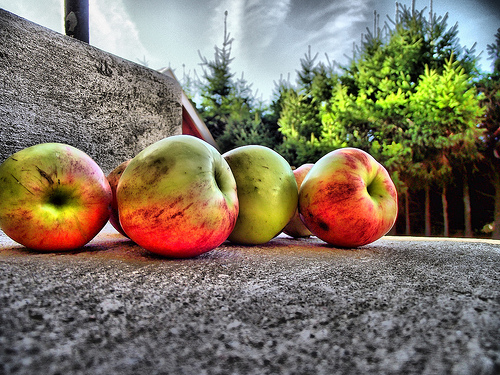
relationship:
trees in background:
[181, 1, 498, 241] [3, 0, 498, 238]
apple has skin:
[221, 145, 298, 246] [222, 143, 298, 247]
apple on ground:
[221, 145, 298, 246] [0, 237, 498, 372]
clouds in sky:
[3, 1, 500, 113] [1, 2, 496, 113]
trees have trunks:
[181, 1, 498, 241] [404, 175, 500, 238]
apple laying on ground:
[221, 145, 298, 246] [0, 237, 498, 372]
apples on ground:
[0, 133, 399, 258] [0, 237, 498, 372]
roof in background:
[162, 65, 224, 153] [3, 0, 498, 238]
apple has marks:
[221, 145, 298, 246] [116, 156, 179, 206]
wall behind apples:
[1, 6, 184, 180] [0, 133, 399, 258]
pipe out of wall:
[65, 0, 89, 46] [1, 6, 184, 180]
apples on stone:
[0, 133, 399, 258] [3, 233, 499, 373]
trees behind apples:
[181, 1, 498, 241] [0, 133, 399, 258]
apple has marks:
[116, 135, 240, 260] [116, 156, 179, 206]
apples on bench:
[0, 133, 399, 258] [3, 6, 500, 374]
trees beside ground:
[181, 1, 498, 241] [0, 237, 498, 372]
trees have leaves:
[181, 1, 498, 241] [181, 3, 499, 191]